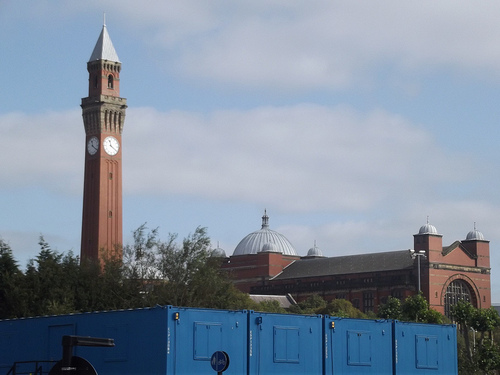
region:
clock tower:
[64, 31, 138, 265]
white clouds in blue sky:
[195, 25, 263, 83]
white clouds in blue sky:
[355, 151, 386, 169]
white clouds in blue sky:
[284, 46, 329, 96]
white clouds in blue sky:
[168, 123, 258, 197]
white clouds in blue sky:
[178, 36, 240, 98]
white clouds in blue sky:
[361, 51, 425, 122]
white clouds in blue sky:
[251, 111, 319, 185]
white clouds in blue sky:
[328, 71, 375, 132]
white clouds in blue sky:
[405, 171, 469, 199]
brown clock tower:
[74, 11, 139, 275]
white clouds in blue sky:
[161, 98, 193, 163]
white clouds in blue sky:
[301, 161, 369, 203]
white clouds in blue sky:
[404, 61, 431, 82]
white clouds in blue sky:
[270, 65, 340, 116]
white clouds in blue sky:
[162, 83, 214, 128]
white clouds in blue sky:
[224, 68, 286, 119]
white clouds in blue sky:
[351, 125, 405, 176]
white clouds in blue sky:
[34, 119, 61, 161]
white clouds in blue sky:
[208, 45, 259, 92]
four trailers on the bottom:
[6, 312, 459, 372]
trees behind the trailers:
[0, 268, 490, 370]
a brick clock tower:
[80, 11, 121, 276]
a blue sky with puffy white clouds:
[1, 7, 491, 237]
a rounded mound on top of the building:
[222, 206, 307, 256]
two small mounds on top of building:
[410, 218, 490, 238]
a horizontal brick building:
[181, 212, 487, 307]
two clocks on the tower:
[83, 137, 120, 153]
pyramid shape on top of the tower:
[81, 7, 132, 65]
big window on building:
[439, 272, 479, 318]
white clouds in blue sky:
[124, 28, 169, 66]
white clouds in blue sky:
[257, 158, 298, 190]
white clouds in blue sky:
[170, 118, 231, 172]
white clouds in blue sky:
[24, 163, 58, 210]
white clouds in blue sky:
[5, 28, 33, 66]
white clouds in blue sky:
[195, 66, 249, 116]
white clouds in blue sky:
[312, 112, 357, 164]